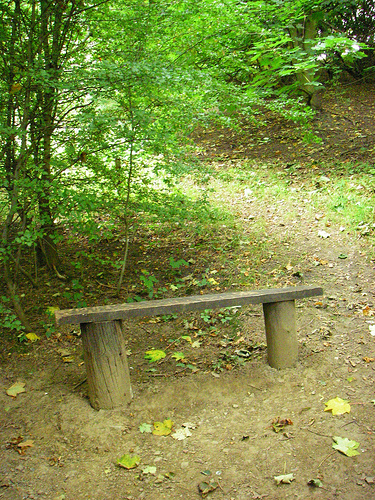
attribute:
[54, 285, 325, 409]
bench — brown, wooden, log, old fashioned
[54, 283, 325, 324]
seat — wood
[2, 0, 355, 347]
tree — thin, green colored, green, leafy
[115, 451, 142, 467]
leaf — fallen, yellow, dry, yellow colored, orange, crumpled, green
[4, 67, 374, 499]
ground — dirt, brown, path, beaten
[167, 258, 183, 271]
leaf — green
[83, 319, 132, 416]
log — circular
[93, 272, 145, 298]
stick — fallen